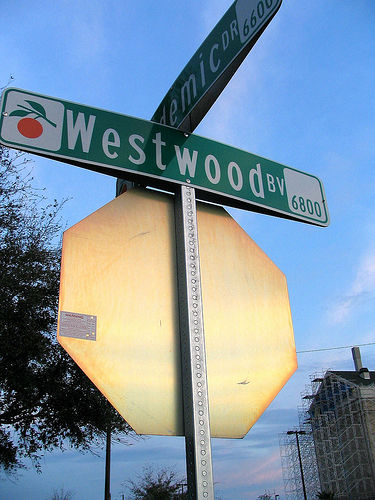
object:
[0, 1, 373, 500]
sky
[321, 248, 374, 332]
cloud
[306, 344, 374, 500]
building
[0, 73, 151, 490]
tree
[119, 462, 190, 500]
tree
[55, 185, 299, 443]
sign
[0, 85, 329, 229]
sign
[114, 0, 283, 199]
sign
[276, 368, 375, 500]
scaffolding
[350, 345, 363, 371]
chimney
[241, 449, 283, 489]
cloud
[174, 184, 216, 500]
pole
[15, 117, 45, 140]
orange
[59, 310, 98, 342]
label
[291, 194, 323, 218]
6800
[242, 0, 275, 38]
6600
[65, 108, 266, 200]
word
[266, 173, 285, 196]
word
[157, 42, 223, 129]
word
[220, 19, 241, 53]
word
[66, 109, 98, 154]
letter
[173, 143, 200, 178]
letter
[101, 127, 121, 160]
letter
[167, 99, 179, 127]
letter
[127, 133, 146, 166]
letter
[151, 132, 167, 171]
letter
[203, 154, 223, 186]
letter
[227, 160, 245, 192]
letter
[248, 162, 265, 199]
letter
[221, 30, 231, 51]
letter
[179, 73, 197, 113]
letter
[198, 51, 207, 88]
letter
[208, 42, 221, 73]
letter